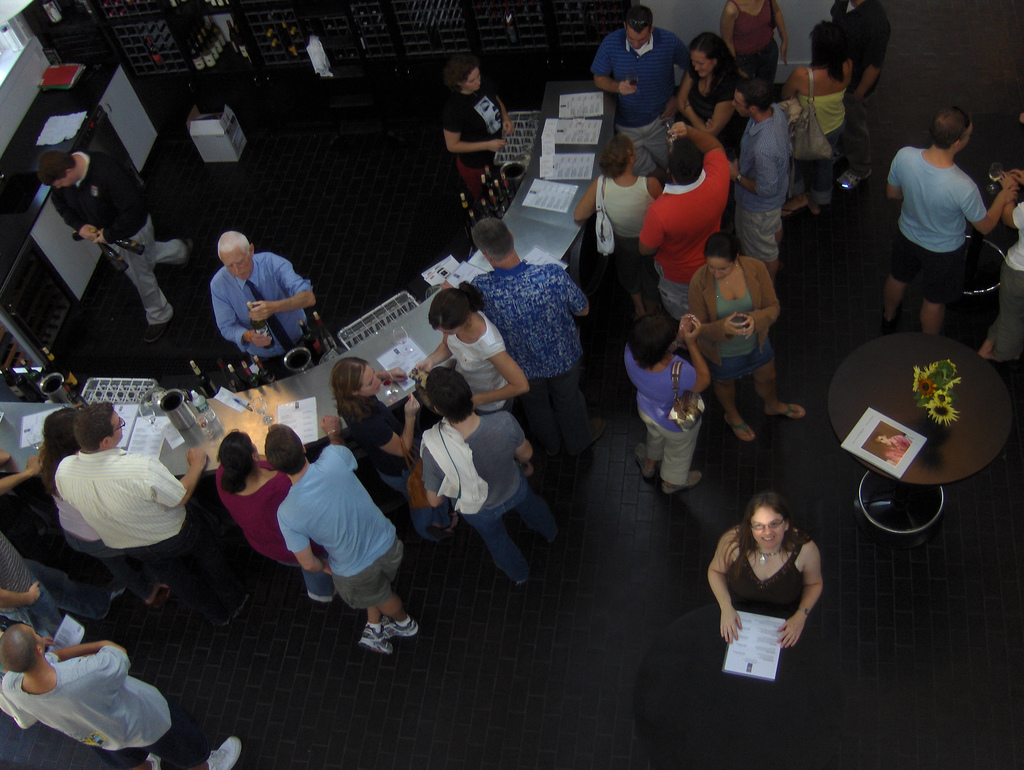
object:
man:
[203, 227, 326, 372]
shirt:
[208, 250, 314, 360]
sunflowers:
[922, 399, 961, 427]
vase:
[923, 407, 955, 435]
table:
[826, 331, 1014, 549]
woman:
[706, 490, 827, 653]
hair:
[216, 229, 251, 257]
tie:
[247, 275, 296, 358]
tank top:
[725, 525, 810, 619]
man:
[258, 410, 430, 662]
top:
[261, 423, 306, 474]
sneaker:
[354, 621, 397, 659]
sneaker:
[377, 615, 420, 639]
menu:
[720, 605, 789, 682]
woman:
[208, 425, 317, 581]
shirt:
[213, 457, 309, 565]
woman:
[712, 0, 792, 96]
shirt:
[729, 0, 775, 54]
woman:
[781, 17, 856, 218]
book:
[833, 398, 931, 479]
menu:
[515, 177, 586, 218]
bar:
[0, 71, 624, 494]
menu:
[536, 147, 601, 185]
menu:
[544, 116, 612, 150]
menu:
[558, 88, 608, 122]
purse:
[591, 172, 621, 260]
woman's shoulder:
[591, 171, 618, 190]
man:
[636, 114, 737, 327]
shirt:
[638, 146, 733, 291]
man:
[32, 141, 208, 347]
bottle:
[92, 228, 147, 256]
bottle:
[97, 240, 130, 274]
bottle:
[488, 189, 504, 219]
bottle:
[468, 210, 478, 252]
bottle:
[457, 190, 472, 244]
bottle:
[494, 179, 511, 208]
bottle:
[474, 174, 489, 205]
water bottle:
[189, 389, 218, 423]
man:
[454, 211, 605, 470]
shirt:
[469, 257, 590, 380]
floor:
[8, 5, 1021, 768]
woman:
[621, 307, 725, 502]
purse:
[666, 357, 709, 438]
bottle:
[246, 302, 275, 351]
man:
[868, 96, 1011, 350]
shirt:
[885, 145, 985, 254]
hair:
[729, 486, 809, 556]